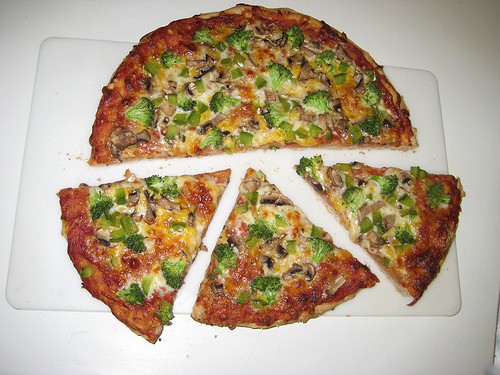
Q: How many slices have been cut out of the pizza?
A: Three.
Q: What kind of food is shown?
A: Pizza.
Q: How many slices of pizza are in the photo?
A: 3.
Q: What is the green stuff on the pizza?
A: Broccoli.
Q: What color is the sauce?
A: Red.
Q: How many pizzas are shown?
A: 1.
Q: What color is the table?
A: White.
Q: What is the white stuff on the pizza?
A: Cheese.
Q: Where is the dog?
A: There isn't one.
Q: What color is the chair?
A: There is no chair in the photo.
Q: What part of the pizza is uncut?
A: Half.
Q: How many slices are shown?
A: Three.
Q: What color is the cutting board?
A: White.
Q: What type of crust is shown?
A: Thin.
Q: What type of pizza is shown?
A: Veggie.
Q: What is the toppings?
A: Mushrooms, cheese, and broccoli.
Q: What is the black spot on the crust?
A: Burnt.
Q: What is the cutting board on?
A: Table.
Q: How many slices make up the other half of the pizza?
A: Three.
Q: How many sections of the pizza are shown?
A: Four.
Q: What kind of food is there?
A: Pizza.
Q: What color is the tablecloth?
A: White.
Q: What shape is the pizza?
A: Triangular.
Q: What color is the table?
A: White.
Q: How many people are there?
A: None.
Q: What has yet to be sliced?
A: Top half of pizza.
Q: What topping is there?
A: Broccoli.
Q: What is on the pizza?
A: Toppings.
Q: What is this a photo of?
A: Food.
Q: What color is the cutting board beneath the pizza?
A: White.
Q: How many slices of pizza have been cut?
A: 3.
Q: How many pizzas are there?
A: 1.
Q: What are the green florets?
A: Broccoli.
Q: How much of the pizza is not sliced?
A: 1/2.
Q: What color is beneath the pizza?
A: White.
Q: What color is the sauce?
A: Red.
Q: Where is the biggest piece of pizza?
A: On top.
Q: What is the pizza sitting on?
A: Cutting board.